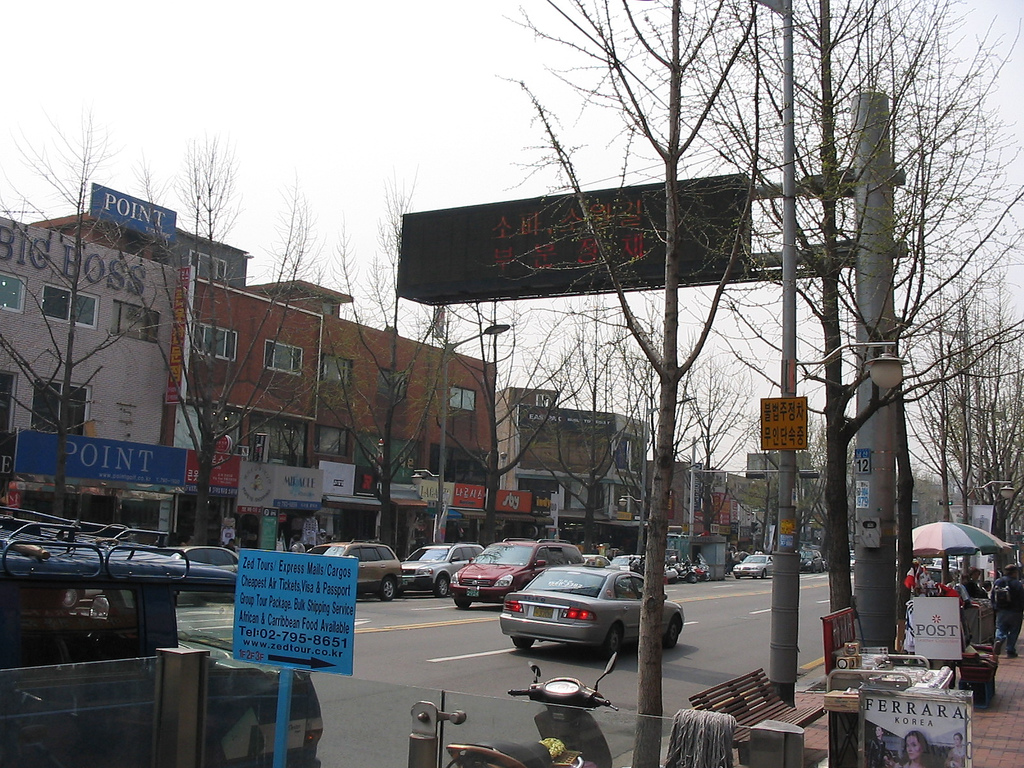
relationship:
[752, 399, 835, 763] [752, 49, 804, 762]
pole with light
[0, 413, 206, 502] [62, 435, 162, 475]
blue sign that says point